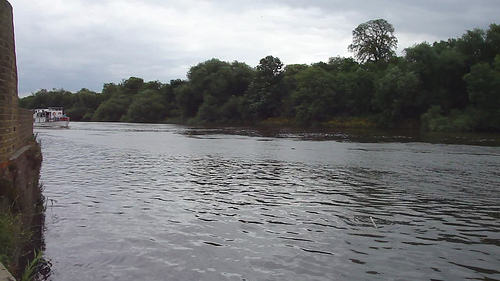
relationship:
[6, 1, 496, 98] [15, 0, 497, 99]
clouds in sky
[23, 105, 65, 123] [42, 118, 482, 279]
building near river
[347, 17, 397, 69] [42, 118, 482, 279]
green tree near river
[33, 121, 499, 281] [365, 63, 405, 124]
river near trees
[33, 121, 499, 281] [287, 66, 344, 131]
river near trees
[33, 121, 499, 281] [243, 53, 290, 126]
river near trees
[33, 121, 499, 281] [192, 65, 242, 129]
river near trees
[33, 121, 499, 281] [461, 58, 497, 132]
river near trees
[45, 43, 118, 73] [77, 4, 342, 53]
cloud in sky